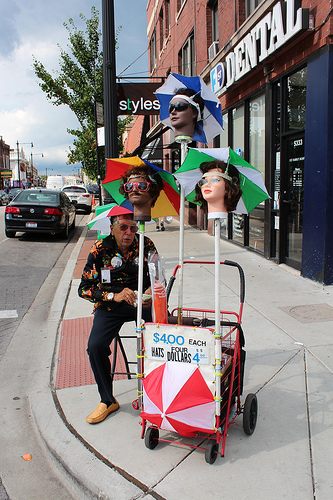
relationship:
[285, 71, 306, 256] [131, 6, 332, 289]
window attached to building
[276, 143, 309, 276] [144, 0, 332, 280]
window attached to building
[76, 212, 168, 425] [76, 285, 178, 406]
man sitting in chair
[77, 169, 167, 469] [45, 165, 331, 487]
man on sidewalk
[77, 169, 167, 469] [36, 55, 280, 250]
man selling umbrella hats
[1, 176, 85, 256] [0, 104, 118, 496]
car on side of street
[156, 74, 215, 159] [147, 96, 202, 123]
mannequin head wearing sun glasses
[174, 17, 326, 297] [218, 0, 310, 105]
shop storefront has a sign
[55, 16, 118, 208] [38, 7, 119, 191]
tree has leaves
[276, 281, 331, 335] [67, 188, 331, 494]
man hole on sidewalk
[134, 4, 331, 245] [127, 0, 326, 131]
building made of bricks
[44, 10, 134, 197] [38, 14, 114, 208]
leaves on tree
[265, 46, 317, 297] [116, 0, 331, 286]
window on building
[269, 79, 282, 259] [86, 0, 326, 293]
window on building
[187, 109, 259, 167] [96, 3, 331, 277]
window on building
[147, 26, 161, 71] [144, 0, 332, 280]
window on building